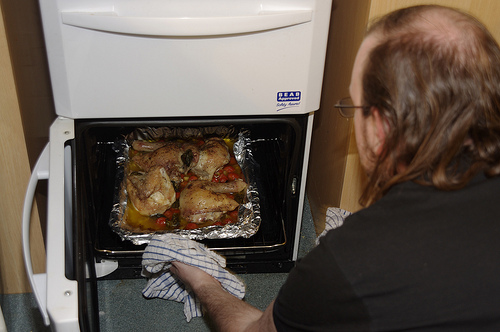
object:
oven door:
[18, 101, 83, 330]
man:
[165, 3, 498, 332]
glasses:
[335, 97, 366, 118]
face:
[348, 51, 387, 169]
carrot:
[230, 211, 237, 217]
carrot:
[163, 210, 173, 218]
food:
[121, 129, 246, 231]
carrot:
[155, 217, 167, 225]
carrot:
[228, 172, 239, 180]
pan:
[89, 132, 285, 255]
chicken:
[127, 138, 239, 225]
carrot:
[185, 223, 197, 229]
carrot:
[214, 222, 220, 226]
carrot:
[188, 176, 199, 181]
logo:
[276, 89, 305, 108]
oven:
[17, 0, 332, 332]